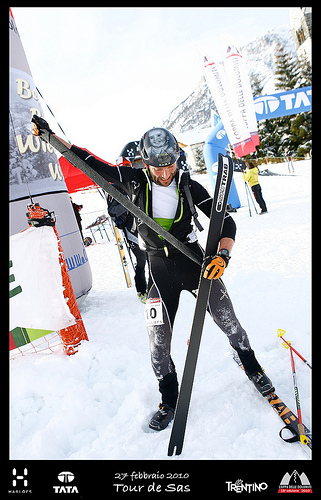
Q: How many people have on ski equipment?
A: One.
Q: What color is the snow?
A: White.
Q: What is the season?
A: Winter.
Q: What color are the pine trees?
A: Green.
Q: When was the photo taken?
A: Daytime.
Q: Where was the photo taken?
A: Ski Resort.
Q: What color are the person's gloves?
A: Yellow.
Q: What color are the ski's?
A: Black.